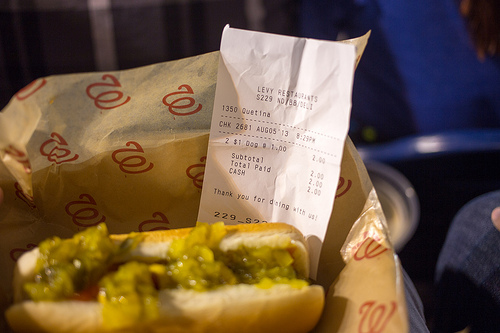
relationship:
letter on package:
[102, 133, 163, 183] [3, 29, 431, 331]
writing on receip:
[251, 83, 318, 107] [193, 15, 358, 255]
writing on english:
[249, 80, 318, 112] [217, 73, 331, 224]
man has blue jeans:
[426, 128, 497, 331] [426, 188, 499, 330]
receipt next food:
[186, 23, 356, 297] [3, 216, 325, 331]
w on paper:
[84, 68, 130, 113] [2, 27, 412, 331]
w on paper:
[103, 138, 154, 178] [2, 27, 412, 331]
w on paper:
[161, 84, 201, 116] [2, 27, 412, 331]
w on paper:
[351, 228, 389, 260] [2, 27, 412, 331]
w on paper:
[356, 295, 396, 331] [2, 27, 412, 331]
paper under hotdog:
[2, 27, 412, 331] [6, 226, 323, 328]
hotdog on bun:
[17, 259, 327, 294] [12, 221, 320, 330]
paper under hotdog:
[212, 86, 331, 226] [14, 217, 325, 331]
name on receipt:
[246, 81, 326, 111] [186, 23, 356, 297]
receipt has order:
[196, 23, 359, 284] [228, 151, 273, 177]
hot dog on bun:
[28, 250, 303, 290] [2, 214, 329, 330]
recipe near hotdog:
[197, 13, 367, 232] [19, 212, 310, 329]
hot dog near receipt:
[13, 250, 320, 307] [185, 15, 377, 285]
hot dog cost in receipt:
[5, 220, 325, 330] [186, 23, 356, 297]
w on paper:
[85, 73, 133, 110] [2, 27, 412, 331]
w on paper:
[111, 141, 154, 175] [2, 27, 412, 331]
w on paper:
[35, 129, 79, 164] [2, 27, 412, 331]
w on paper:
[60, 190, 107, 228] [2, 27, 412, 331]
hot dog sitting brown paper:
[5, 220, 325, 330] [1, 30, 429, 332]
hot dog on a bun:
[14, 213, 329, 331] [12, 221, 320, 330]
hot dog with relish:
[14, 213, 329, 331] [24, 226, 295, 327]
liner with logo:
[24, 98, 153, 178] [163, 82, 202, 116]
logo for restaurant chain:
[102, 134, 161, 183] [86, 67, 136, 137]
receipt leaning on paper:
[196, 23, 359, 284] [2, 27, 412, 331]